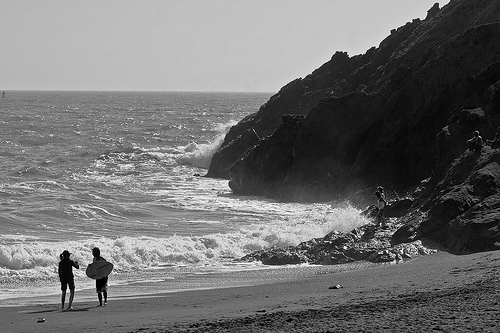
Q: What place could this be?
A: It is a beach.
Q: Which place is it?
A: It is a beach.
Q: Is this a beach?
A: Yes, it is a beach.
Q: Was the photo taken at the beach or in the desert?
A: It was taken at the beach.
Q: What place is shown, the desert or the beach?
A: It is the beach.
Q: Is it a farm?
A: No, it is a beach.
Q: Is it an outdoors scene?
A: Yes, it is outdoors.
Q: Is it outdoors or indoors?
A: It is outdoors.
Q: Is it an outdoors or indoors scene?
A: It is outdoors.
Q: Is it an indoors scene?
A: No, it is outdoors.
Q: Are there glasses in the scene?
A: No, there are no glasses.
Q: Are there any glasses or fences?
A: No, there are no glasses or fences.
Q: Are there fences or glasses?
A: No, there are no glasses or fences.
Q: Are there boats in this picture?
A: No, there are no boats.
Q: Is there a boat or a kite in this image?
A: No, there are no boats or kites.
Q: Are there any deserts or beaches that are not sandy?
A: No, there is a beach but it is sandy.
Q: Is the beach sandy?
A: Yes, the beach is sandy.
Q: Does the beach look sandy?
A: Yes, the beach is sandy.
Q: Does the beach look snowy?
A: No, the beach is sandy.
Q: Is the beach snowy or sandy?
A: The beach is sandy.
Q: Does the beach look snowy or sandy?
A: The beach is sandy.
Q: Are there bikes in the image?
A: No, there are no bikes.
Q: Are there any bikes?
A: No, there are no bikes.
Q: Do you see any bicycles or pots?
A: No, there are no bicycles or pots.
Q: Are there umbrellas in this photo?
A: No, there are no umbrellas.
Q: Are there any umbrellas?
A: No, there are no umbrellas.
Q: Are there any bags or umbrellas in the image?
A: No, there are no umbrellas or bags.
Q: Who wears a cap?
A: The people wear a cap.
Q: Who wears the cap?
A: The people wear a cap.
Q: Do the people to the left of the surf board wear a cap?
A: Yes, the people wear a cap.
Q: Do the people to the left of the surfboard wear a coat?
A: No, the people wear a cap.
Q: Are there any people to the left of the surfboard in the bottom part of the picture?
A: Yes, there are people to the left of the surfboard.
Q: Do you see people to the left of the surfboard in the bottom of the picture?
A: Yes, there are people to the left of the surfboard.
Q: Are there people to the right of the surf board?
A: No, the people are to the left of the surf board.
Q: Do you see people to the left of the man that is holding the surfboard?
A: Yes, there are people to the left of the man.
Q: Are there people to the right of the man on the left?
A: No, the people are to the left of the man.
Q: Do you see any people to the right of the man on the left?
A: No, the people are to the left of the man.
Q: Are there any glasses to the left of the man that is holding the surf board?
A: No, there are people to the left of the man.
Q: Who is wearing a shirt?
A: The people are wearing a shirt.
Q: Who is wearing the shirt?
A: The people are wearing a shirt.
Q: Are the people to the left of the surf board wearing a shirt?
A: Yes, the people are wearing a shirt.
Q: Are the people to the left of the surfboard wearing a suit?
A: No, the people are wearing a shirt.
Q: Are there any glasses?
A: No, there are no glasses.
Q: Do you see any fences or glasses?
A: No, there are no glasses or fences.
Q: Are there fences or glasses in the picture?
A: No, there are no glasses or fences.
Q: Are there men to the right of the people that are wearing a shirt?
A: Yes, there is a man to the right of the people.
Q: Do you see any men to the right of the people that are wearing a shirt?
A: Yes, there is a man to the right of the people.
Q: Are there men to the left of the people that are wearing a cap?
A: No, the man is to the right of the people.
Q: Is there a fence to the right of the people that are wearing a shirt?
A: No, there is a man to the right of the people.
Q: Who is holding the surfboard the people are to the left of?
A: The man is holding the surf board.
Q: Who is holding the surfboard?
A: The man is holding the surf board.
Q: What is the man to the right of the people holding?
A: The man is holding the surfboard.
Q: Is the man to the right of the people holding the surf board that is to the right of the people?
A: Yes, the man is holding the surfboard.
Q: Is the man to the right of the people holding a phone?
A: No, the man is holding the surfboard.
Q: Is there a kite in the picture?
A: No, there are no kites.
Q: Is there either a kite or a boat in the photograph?
A: No, there are no kites or boats.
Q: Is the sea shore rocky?
A: Yes, the sea shore is rocky.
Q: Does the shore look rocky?
A: Yes, the shore is rocky.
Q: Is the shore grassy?
A: No, the shore is rocky.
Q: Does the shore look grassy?
A: No, the shore is rocky.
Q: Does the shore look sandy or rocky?
A: The shore is rocky.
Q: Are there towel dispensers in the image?
A: No, there are no towel dispensers.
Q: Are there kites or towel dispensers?
A: No, there are no towel dispensers or kites.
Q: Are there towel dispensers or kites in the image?
A: No, there are no towel dispensers or kites.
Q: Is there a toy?
A: No, there are no toys.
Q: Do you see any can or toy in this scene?
A: No, there are no toys or cans.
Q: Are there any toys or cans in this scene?
A: No, there are no toys or cans.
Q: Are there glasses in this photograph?
A: No, there are no glasses.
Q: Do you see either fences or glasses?
A: No, there are no glasses or fences.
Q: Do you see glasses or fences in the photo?
A: No, there are no glasses or fences.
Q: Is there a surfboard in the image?
A: Yes, there is a surfboard.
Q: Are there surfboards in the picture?
A: Yes, there is a surfboard.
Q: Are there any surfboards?
A: Yes, there is a surfboard.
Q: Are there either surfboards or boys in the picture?
A: Yes, there is a surfboard.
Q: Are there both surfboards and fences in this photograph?
A: No, there is a surfboard but no fences.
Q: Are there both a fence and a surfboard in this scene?
A: No, there is a surfboard but no fences.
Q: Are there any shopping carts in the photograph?
A: No, there are no shopping carts.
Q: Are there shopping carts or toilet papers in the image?
A: No, there are no shopping carts or toilet papers.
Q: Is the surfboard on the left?
A: Yes, the surfboard is on the left of the image.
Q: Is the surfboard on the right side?
A: No, the surfboard is on the left of the image.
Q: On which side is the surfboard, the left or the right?
A: The surfboard is on the left of the image.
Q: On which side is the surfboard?
A: The surfboard is on the left of the image.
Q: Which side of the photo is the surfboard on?
A: The surfboard is on the left of the image.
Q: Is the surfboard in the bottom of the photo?
A: Yes, the surfboard is in the bottom of the image.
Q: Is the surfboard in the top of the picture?
A: No, the surfboard is in the bottom of the image.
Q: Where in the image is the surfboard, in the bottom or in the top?
A: The surfboard is in the bottom of the image.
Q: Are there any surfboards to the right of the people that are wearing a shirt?
A: Yes, there is a surfboard to the right of the people.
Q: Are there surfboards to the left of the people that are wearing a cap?
A: No, the surfboard is to the right of the people.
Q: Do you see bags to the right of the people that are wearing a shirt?
A: No, there is a surfboard to the right of the people.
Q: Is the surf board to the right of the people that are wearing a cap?
A: Yes, the surf board is to the right of the people.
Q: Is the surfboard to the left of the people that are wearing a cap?
A: No, the surfboard is to the right of the people.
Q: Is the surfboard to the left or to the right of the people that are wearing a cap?
A: The surfboard is to the right of the people.